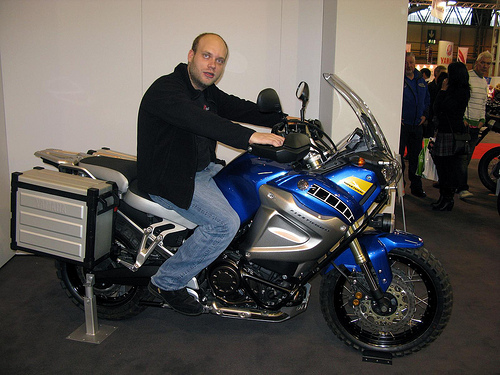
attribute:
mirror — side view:
[291, 73, 316, 129]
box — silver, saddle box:
[7, 165, 127, 264]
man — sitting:
[137, 31, 306, 317]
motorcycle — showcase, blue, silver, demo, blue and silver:
[11, 75, 454, 361]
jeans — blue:
[138, 167, 255, 320]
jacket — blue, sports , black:
[133, 62, 288, 213]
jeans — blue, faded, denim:
[124, 161, 329, 347]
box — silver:
[6, 164, 117, 266]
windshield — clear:
[323, 70, 393, 162]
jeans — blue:
[150, 157, 247, 297]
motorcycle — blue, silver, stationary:
[14, 105, 489, 362]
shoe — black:
[145, 278, 203, 316]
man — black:
[152, 41, 232, 191]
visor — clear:
[320, 70, 397, 161]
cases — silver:
[9, 155, 113, 270]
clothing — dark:
[438, 86, 468, 195]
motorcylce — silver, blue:
[16, 73, 455, 361]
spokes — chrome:
[354, 289, 376, 324]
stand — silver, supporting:
[65, 270, 123, 344]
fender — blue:
[326, 225, 426, 289]